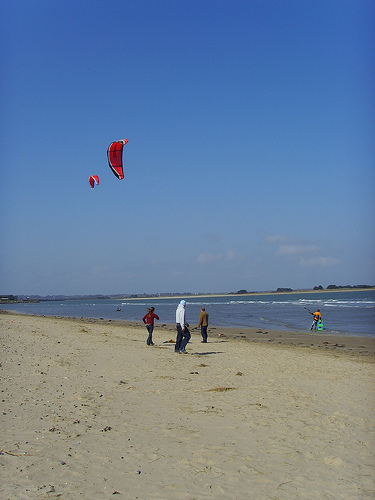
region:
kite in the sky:
[98, 139, 147, 187]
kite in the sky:
[71, 159, 101, 193]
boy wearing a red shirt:
[132, 294, 159, 348]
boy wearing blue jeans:
[131, 294, 155, 345]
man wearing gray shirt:
[166, 294, 189, 349]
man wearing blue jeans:
[167, 295, 195, 365]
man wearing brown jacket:
[193, 302, 217, 344]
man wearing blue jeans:
[195, 295, 218, 350]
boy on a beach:
[126, 296, 164, 346]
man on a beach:
[196, 300, 208, 340]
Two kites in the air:
[81, 136, 130, 191]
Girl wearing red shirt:
[141, 304, 160, 348]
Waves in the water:
[192, 298, 373, 307]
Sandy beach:
[170, 431, 253, 474]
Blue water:
[236, 308, 283, 326]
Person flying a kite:
[300, 302, 326, 333]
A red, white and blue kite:
[103, 136, 131, 181]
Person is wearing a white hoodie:
[171, 299, 192, 359]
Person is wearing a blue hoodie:
[174, 298, 188, 308]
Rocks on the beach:
[42, 407, 120, 450]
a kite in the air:
[97, 136, 138, 183]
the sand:
[184, 425, 282, 485]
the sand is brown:
[223, 379, 282, 444]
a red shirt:
[144, 311, 157, 324]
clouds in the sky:
[274, 227, 337, 271]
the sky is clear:
[222, 135, 280, 184]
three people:
[134, 299, 227, 361]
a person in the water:
[308, 305, 330, 329]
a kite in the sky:
[82, 173, 110, 193]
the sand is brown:
[233, 424, 309, 470]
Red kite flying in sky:
[104, 137, 133, 182]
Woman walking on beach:
[139, 306, 158, 346]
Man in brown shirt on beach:
[197, 306, 209, 340]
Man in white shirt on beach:
[175, 300, 190, 354]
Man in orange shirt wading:
[304, 305, 319, 332]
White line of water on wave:
[237, 295, 373, 305]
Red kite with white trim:
[86, 174, 99, 188]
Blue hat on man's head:
[181, 300, 186, 304]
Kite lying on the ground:
[162, 338, 175, 343]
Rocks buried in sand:
[37, 392, 80, 425]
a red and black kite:
[83, 104, 153, 182]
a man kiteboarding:
[294, 299, 334, 339]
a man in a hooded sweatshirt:
[165, 299, 192, 330]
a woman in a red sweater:
[134, 309, 164, 332]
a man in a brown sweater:
[196, 307, 210, 328]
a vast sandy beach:
[58, 358, 325, 479]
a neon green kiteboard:
[316, 317, 328, 334]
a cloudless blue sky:
[173, 55, 324, 130]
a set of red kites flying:
[57, 123, 150, 200]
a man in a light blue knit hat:
[171, 298, 194, 317]